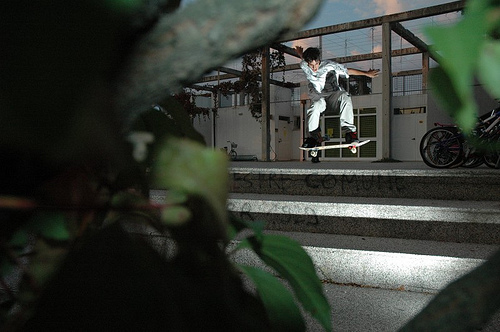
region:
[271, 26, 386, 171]
This is a person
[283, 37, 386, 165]
This is a person skating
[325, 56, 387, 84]
This is a hand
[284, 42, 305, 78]
This is a hand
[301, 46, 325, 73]
This is a head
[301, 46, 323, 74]
This is a head of a person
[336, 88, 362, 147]
This is a leg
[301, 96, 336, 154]
This is a leg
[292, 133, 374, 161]
This is a skating board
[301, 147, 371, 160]
Wheels of a skating board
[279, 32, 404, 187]
a boy skateboarding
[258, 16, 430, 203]
a boy skateboarding on stairs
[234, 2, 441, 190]
a boy on a skateboard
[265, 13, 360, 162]
a boy with his feet on a skateboard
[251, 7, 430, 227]
a boy with his arms up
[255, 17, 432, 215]
a boy wearing a shirt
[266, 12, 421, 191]
a boy wearing pants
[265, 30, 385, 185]
a boy wearing shoes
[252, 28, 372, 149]
a boy skateboarding outside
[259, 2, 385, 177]
skatebording outside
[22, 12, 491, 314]
A skateboarder performing a trick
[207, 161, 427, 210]
Graffiti on the steps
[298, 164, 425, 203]
The writing says "comune"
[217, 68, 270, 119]
Plants hanging from the ceiling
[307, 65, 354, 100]
A white shirt on the boy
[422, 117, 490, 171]
Multiple bikes parked near the steps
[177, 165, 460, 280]
Three grey stairs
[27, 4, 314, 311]
A large green plant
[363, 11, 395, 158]
A tall metal pole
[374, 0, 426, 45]
White cloud in the sky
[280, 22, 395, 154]
the man is skateboarding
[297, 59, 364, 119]
man's shirt is white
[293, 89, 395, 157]
man's pants are white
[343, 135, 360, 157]
skateboard wheel is red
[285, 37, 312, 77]
man's arm extended behind him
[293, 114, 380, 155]
man's shoes are black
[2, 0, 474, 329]
picture taken behind plants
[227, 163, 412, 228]
spray painted letters on steps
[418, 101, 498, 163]
motorcycle near the man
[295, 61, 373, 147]
light shining on man's clothes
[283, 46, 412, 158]
boy is on skateboard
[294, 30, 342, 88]
boy has dark hair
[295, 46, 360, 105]
boy has white shirt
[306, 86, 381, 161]
boy has white pants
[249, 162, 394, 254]
boy on grey steps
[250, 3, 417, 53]
metal fencing behind boy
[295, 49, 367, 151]
boy jumping on skateboard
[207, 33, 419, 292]
camera looking through opening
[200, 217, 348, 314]
green leaves in front of boy